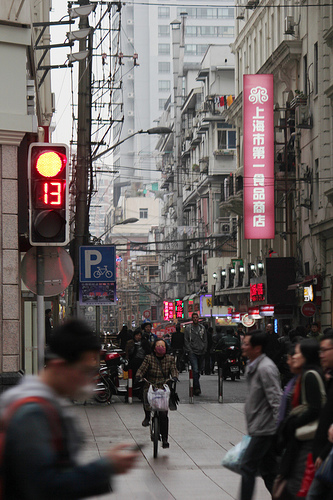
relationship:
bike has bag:
[140, 378, 175, 457] [147, 384, 171, 411]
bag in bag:
[148, 384, 170, 412] [147, 384, 171, 411]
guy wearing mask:
[2, 322, 138, 499] [80, 381, 96, 402]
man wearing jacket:
[139, 340, 175, 456] [138, 355, 179, 384]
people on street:
[0, 318, 332, 500] [70, 306, 329, 498]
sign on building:
[242, 73, 276, 239] [216, 1, 332, 307]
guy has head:
[2, 322, 138, 499] [43, 321, 101, 400]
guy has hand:
[2, 322, 138, 499] [109, 443, 138, 474]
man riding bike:
[139, 340, 175, 456] [140, 378, 175, 457]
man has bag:
[139, 340, 175, 456] [148, 384, 170, 412]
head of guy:
[43, 321, 101, 400] [2, 322, 138, 499]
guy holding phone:
[2, 322, 138, 499] [133, 442, 145, 456]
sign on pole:
[78, 243, 118, 285] [95, 306, 101, 343]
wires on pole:
[92, 233, 234, 253] [76, 1, 97, 308]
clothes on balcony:
[217, 95, 232, 106] [206, 94, 234, 117]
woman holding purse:
[287, 339, 326, 440] [297, 419, 323, 439]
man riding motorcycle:
[217, 330, 240, 353] [223, 347, 241, 380]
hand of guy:
[109, 443, 138, 474] [2, 322, 138, 499]